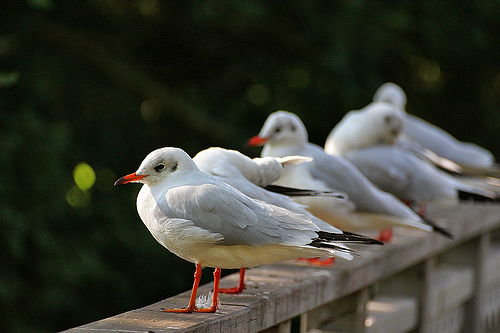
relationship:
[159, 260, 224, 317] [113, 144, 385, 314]
red legs of bird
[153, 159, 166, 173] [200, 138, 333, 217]
eye of bird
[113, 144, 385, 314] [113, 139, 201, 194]
bird has white head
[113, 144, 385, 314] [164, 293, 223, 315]
bird has orange feet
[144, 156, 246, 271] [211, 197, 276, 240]
bird has wing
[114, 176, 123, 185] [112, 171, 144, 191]
tip on beak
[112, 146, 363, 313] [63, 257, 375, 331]
bird resting on rail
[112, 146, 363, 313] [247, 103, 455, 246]
bird resting with bird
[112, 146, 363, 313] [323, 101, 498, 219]
bird resting with bird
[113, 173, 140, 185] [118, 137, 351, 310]
beak on bird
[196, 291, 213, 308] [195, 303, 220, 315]
feather by foot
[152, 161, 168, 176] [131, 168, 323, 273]
eye of bird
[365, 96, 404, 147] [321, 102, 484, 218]
head belonging to bird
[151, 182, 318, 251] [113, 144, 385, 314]
wing belonging to bird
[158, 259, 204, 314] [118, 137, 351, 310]
leg belonging to bird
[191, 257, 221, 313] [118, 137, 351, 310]
leg belonging to bird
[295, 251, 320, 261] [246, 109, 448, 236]
leg belonging to bird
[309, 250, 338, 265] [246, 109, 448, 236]
leg belonging to bird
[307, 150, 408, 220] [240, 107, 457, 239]
wing belonging to bird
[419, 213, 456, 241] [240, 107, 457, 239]
tail feather belonging to bird